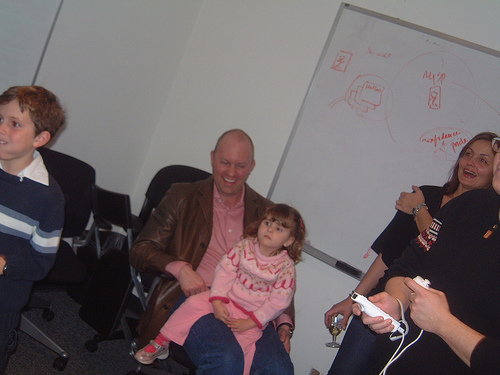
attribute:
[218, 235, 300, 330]
sweater — pink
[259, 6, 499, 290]
board — dry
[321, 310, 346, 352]
beverage — alcoholic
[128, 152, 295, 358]
brown jacket — red, leather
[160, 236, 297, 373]
outfit — pink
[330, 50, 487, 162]
writing — red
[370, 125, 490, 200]
woman — smiling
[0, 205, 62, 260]
stripe — white, blue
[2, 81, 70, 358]
boy — blue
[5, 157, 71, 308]
shirt — white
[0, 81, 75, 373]
boy — little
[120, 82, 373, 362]
person — playing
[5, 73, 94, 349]
boy — standing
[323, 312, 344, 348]
glass — small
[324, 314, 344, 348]
glass — half-full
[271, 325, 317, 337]
wristwatch — small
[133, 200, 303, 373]
child — small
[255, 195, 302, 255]
hair — red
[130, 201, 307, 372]
girl — little, red-headed, wearing pink, sitting